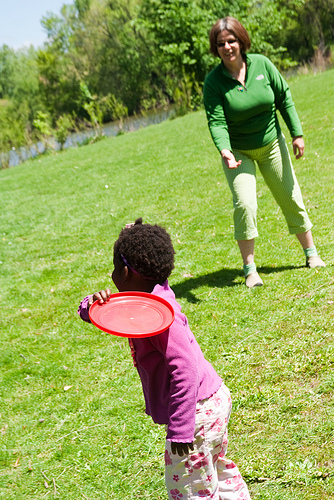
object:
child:
[79, 217, 249, 500]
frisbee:
[89, 291, 176, 338]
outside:
[0, 0, 334, 500]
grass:
[0, 68, 333, 500]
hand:
[89, 288, 111, 305]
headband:
[121, 222, 159, 281]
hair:
[114, 217, 176, 281]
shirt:
[76, 280, 222, 443]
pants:
[165, 383, 254, 500]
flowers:
[164, 385, 251, 500]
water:
[0, 102, 180, 170]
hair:
[210, 17, 251, 57]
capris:
[221, 133, 315, 241]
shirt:
[203, 53, 302, 154]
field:
[8, 68, 333, 494]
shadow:
[170, 264, 308, 304]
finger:
[223, 154, 231, 161]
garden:
[0, 0, 334, 500]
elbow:
[208, 115, 227, 129]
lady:
[203, 18, 325, 289]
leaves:
[24, 178, 127, 493]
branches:
[247, 470, 328, 485]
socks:
[244, 246, 326, 288]